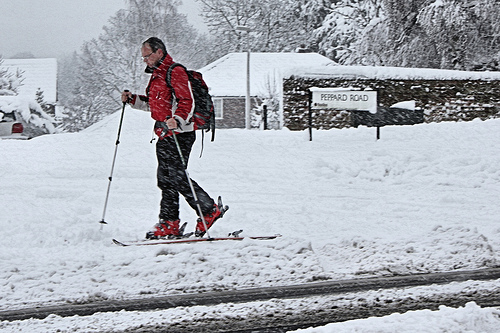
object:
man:
[120, 35, 230, 240]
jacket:
[127, 53, 199, 141]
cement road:
[0, 266, 500, 333]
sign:
[307, 86, 380, 142]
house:
[193, 50, 344, 131]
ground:
[0, 118, 500, 332]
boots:
[145, 219, 181, 240]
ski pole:
[97, 88, 130, 224]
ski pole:
[165, 114, 212, 240]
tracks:
[0, 264, 500, 321]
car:
[0, 94, 57, 140]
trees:
[413, 0, 500, 72]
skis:
[110, 232, 284, 247]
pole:
[243, 51, 251, 130]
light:
[234, 26, 253, 32]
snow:
[122, 32, 231, 241]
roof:
[193, 51, 340, 97]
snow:
[0, 0, 500, 333]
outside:
[0, 0, 500, 333]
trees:
[66, 0, 199, 111]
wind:
[33, 31, 114, 90]